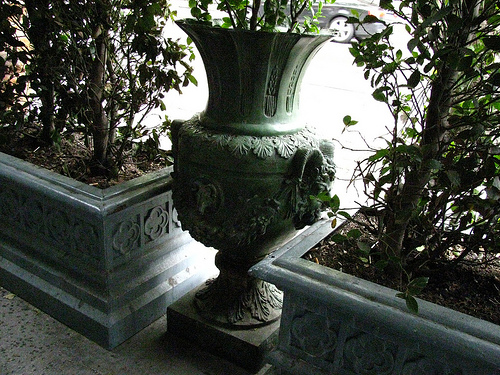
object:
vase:
[157, 16, 347, 333]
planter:
[0, 122, 224, 355]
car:
[239, 0, 402, 48]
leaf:
[394, 292, 421, 315]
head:
[183, 179, 224, 216]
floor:
[1, 286, 275, 374]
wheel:
[323, 12, 355, 45]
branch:
[0, 0, 205, 167]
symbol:
[108, 215, 145, 258]